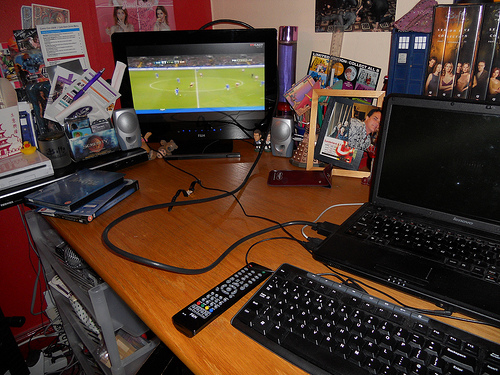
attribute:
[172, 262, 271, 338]
remote — black, long, remote control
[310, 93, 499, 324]
laptop — turned off, black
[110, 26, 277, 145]
monitor — on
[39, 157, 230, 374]
desktop — brown, wooden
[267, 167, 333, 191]
case — dark red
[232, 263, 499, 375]
keyboard — black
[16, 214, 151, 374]
bin — plastic, clear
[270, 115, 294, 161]
speakers — silver, small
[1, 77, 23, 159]
container — open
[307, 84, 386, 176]
frame — wooden, brown, wood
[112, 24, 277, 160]
computer — small, flatscreen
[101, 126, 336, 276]
black cord — long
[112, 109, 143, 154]
speaker — gray, silver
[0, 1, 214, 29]
wall — red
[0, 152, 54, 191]
dvd player — beige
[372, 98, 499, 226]
screen — dark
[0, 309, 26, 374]
chair — metal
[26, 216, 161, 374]
shelving — plastic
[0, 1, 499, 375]
room — cluttered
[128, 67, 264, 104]
field — green